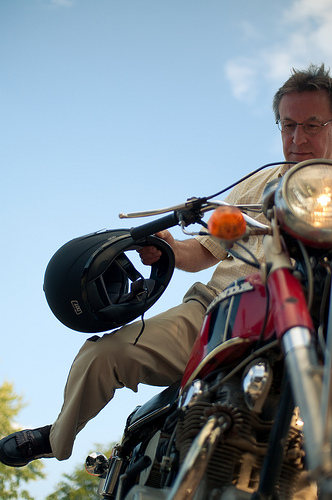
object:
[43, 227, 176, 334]
helmet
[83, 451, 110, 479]
rear light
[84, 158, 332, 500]
bike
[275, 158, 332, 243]
front light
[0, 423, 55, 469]
shoe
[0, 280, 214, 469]
leg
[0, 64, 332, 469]
man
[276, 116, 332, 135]
glasses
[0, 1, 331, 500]
sky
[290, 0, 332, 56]
clouds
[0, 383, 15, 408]
leaves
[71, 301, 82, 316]
logo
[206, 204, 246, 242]
signal light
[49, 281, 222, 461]
slacks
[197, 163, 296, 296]
shirt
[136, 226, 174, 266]
hand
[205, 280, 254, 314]
maker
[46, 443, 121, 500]
tree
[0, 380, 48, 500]
tree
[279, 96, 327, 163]
face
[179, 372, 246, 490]
motor